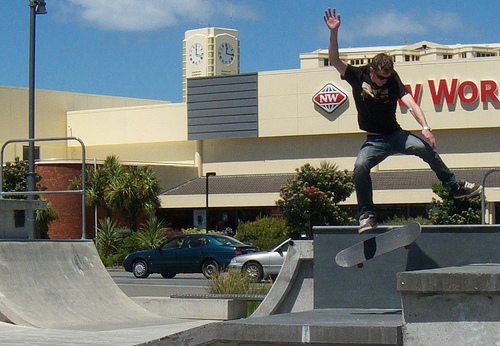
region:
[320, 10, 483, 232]
a man in the air at the skate park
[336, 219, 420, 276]
the mans black skateboard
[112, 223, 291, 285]
the cars driving down the street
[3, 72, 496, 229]
the buildings behind the skate park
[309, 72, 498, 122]
the sign on the wall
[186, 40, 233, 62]
the clocks on the tower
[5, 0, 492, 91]
the partly cloudy blue sky above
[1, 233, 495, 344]
the skate park for the skaters to use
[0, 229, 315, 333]
the half pipe to do tricks on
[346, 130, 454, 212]
the jeans the man is wearing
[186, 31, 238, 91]
yellow clocktower in the distance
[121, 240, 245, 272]
green sedan on street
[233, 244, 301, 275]
silver car on street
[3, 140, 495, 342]
skateboarding park with a ramp and rails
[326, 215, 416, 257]
skateboard in the air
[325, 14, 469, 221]
skateboarder jumping off skateboard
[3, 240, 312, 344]
grey concrete ramp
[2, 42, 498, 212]
large tan building behind skate park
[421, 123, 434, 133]
silver watch on skateboarder's hand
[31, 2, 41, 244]
tall pole with light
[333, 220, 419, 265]
a black, dingy skateboard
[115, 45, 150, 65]
a blue sky above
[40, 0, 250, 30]
a white cloud in the sky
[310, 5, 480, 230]
a male skateboarder doing a trick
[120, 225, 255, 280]
a dark green car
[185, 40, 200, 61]
a black and white clock on building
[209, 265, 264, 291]
tall grass on side of road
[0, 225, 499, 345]
a concrete skateboard ramp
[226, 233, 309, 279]
a silver car on road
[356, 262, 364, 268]
red wheel of skateboard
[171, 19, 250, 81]
There is a White Clock tower on top of a building.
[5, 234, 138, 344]
There is a silver skating rank.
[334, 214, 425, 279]
Grey skateboard up a man's feet.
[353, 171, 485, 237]
A man's feet are in the air.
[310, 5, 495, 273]
A man is doing a skateboard trick.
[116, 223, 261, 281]
There is a Blue car parked.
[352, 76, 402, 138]
The man is wearing a Black shirt.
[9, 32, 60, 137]
There is a Gray pole in the background.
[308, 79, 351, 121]
A store sign with the intials NW.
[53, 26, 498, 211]
The store is White.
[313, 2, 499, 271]
a guy doing jumps on skateboard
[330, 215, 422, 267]
a grey skateboard falling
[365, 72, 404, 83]
a guy wearing sunglasses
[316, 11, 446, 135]
a guy wearing a black shirt doing tricks on skateboard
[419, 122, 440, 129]
a guy wearing a watch on his arm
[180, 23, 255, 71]
a clock on top of a building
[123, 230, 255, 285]
a green car parked next to street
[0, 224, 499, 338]
many jumps at a skate park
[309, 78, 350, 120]
a red and white sign in shape of a diamond on building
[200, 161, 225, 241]
a black light pole on sidewalk